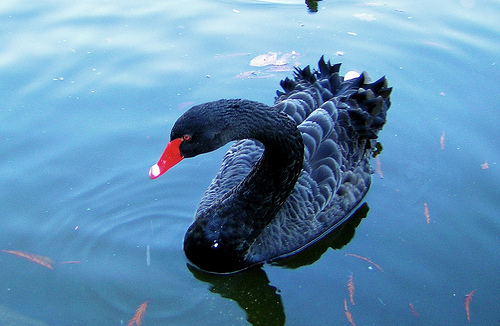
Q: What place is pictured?
A: It is a lake.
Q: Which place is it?
A: It is a lake.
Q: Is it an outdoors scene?
A: Yes, it is outdoors.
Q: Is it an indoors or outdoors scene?
A: It is outdoors.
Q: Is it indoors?
A: No, it is outdoors.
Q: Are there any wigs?
A: No, there are no wigs.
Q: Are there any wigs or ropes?
A: No, there are no wigs or ropes.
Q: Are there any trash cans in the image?
A: No, there are no trash cans.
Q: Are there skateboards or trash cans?
A: No, there are no trash cans or skateboards.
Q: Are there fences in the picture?
A: No, there are no fences.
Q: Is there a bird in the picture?
A: Yes, there is a bird.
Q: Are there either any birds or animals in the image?
A: Yes, there is a bird.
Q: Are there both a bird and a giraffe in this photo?
A: No, there is a bird but no giraffes.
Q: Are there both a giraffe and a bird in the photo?
A: No, there is a bird but no giraffes.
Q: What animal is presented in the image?
A: The animal is a bird.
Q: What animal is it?
A: The animal is a bird.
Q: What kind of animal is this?
A: This is a bird.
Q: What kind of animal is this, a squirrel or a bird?
A: This is a bird.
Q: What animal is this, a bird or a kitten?
A: This is a bird.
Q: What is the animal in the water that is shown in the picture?
A: The animal is a bird.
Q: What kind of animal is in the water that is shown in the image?
A: The animal is a bird.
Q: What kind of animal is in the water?
A: The animal is a bird.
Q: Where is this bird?
A: The bird is in the water.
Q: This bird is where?
A: The bird is in the water.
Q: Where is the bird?
A: The bird is in the water.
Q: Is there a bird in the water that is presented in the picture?
A: Yes, there is a bird in the water.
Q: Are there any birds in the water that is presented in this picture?
A: Yes, there is a bird in the water.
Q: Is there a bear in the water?
A: No, there is a bird in the water.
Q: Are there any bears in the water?
A: No, there is a bird in the water.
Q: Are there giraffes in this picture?
A: No, there are no giraffes.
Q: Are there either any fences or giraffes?
A: No, there are no giraffes or fences.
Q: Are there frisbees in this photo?
A: No, there are no frisbees.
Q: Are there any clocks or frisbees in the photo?
A: No, there are no frisbees or clocks.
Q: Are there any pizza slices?
A: No, there are no pizza slices.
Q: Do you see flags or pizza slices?
A: No, there are no pizza slices or flags.